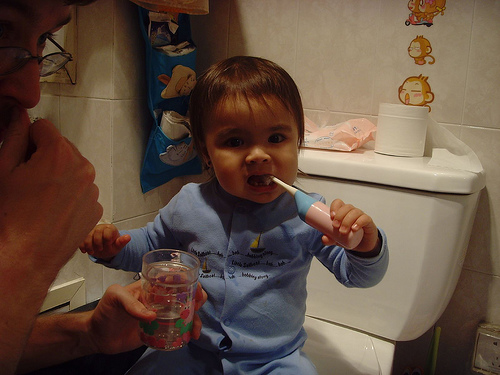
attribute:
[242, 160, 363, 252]
toothbrush — electric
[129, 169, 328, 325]
shirt — blue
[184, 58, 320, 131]
hair — brown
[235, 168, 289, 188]
mouth — baby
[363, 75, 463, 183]
paper — white, toliet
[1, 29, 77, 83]
glasses — rimmed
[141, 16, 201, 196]
organizer — blue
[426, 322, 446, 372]
handle — beige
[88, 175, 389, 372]
clothes — light blue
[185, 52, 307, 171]
hair — brown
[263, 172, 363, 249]
toothbrush — pink, blue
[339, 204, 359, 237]
finger — white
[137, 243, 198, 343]
glass — colorful 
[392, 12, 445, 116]
monkey decals — pair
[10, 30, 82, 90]
glasses — pair